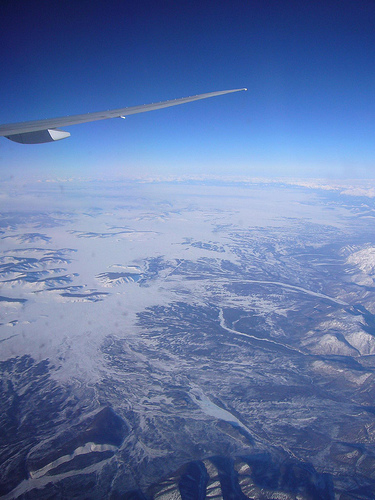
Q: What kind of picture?
A: Aerial.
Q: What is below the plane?
A: Ground.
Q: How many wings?
A: 1.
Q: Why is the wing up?
A: Flying.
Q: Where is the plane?
A: In the air.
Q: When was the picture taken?
A: Daytime.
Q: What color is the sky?
A: Blue.